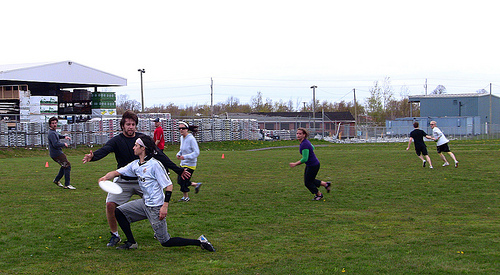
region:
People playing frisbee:
[36, 111, 463, 193]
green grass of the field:
[228, 195, 468, 274]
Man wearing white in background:
[428, 117, 458, 168]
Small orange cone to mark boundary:
[218, 152, 227, 159]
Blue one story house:
[402, 89, 499, 144]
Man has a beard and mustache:
[119, 115, 139, 135]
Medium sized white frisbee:
[98, 177, 125, 197]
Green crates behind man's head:
[94, 90, 118, 110]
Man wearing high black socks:
[53, 162, 75, 184]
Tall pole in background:
[306, 79, 322, 121]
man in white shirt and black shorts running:
[425, 119, 460, 170]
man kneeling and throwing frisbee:
[96, 134, 216, 254]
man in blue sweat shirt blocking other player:
[78, 110, 193, 250]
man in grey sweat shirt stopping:
[43, 115, 78, 193]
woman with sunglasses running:
[172, 120, 203, 203]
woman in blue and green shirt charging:
[286, 125, 331, 207]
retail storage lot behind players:
[2, 86, 288, 145]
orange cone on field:
[220, 152, 225, 160]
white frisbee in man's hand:
[97, 175, 124, 194]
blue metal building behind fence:
[385, 90, 498, 137]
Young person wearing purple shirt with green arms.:
[290, 127, 331, 201]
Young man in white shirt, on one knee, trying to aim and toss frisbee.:
[97, 137, 213, 251]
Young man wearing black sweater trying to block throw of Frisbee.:
[82, 111, 189, 179]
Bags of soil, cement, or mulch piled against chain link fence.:
[2, 112, 289, 145]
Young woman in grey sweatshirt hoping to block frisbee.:
[173, 118, 201, 200]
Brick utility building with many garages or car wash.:
[253, 110, 358, 140]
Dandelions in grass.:
[450, 247, 470, 261]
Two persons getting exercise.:
[405, 118, 461, 172]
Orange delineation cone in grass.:
[216, 151, 229, 164]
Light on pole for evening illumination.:
[308, 83, 320, 144]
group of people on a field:
[24, 105, 482, 264]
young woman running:
[285, 126, 336, 209]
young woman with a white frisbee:
[86, 135, 227, 262]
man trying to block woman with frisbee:
[75, 98, 230, 266]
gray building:
[398, 87, 498, 136]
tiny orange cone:
[40, 158, 52, 171]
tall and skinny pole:
[305, 85, 325, 135]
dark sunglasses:
[175, 125, 190, 133]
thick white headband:
[131, 133, 151, 149]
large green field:
[4, 136, 499, 273]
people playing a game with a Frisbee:
[35, 111, 476, 261]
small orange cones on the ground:
[35, 136, 239, 174]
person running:
[277, 116, 340, 206]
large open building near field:
[0, 59, 130, 170]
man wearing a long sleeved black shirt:
[71, 105, 190, 191]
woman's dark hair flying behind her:
[169, 114, 206, 144]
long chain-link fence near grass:
[0, 111, 497, 156]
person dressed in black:
[396, 112, 432, 161]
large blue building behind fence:
[381, 84, 498, 141]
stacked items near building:
[3, 80, 283, 144]